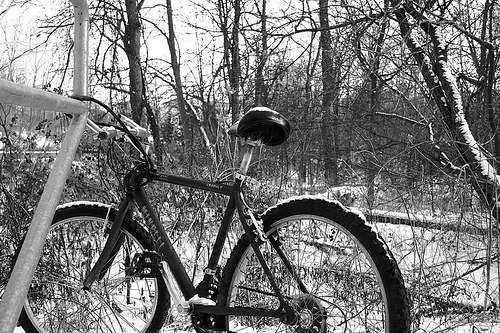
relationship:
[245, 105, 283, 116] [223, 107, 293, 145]
snow on seat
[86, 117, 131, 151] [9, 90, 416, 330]
handlebar on bike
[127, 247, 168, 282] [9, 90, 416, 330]
pedal on bike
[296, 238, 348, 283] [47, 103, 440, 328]
spoke on bike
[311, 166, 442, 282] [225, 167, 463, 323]
snow on tire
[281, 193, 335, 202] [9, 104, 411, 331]
snow on bicycle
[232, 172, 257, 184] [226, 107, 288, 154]
clamp on seat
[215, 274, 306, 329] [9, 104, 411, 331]
chain on bicycle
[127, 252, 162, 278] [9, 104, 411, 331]
pedal on bicycle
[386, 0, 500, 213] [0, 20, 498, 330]
tree covered with snow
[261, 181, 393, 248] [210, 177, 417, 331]
snow on tire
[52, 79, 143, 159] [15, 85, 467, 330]
rope holding bicycle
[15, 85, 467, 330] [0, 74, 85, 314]
bicycle to pole